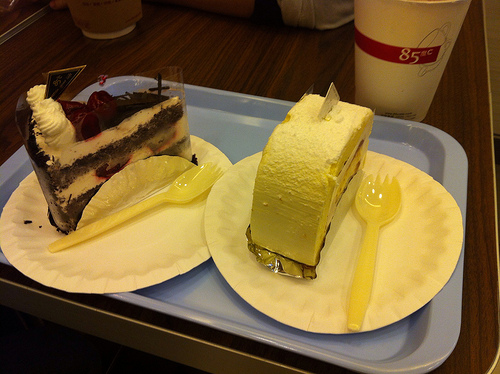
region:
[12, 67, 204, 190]
Dessert on a paper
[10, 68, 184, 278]
Dessert on a paper plate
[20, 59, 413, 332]
Two desserts on paper plates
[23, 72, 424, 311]
Two desserts on a purple tray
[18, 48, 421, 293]
Two desserts with plastic utensils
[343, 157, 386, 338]
A yellow plastic utensil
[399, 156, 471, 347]
A paper plate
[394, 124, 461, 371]
A paper plate on a purple tray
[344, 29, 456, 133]
A paper cup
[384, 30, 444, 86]
White numbers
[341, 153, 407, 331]
a yellow plastic spork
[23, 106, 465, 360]
some white paper plates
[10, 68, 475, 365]
a blue plastic tray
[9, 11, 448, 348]
a few deserts on togo settings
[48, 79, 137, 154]
a few cooked cherries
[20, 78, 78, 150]
some whip cream toppings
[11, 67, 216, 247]
a chocolate layered cake slice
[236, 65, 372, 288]
a yellow cake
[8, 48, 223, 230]
a plastic wrapper on cake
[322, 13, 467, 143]
a disposable cup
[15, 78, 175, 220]
this is a cake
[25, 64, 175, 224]
the cake is brown in color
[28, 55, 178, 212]
the cake is creamy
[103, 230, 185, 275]
this is a plate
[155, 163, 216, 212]
this is spoon beside the cake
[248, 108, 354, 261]
the cake is yellow in color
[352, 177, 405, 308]
the spoon is yellow in color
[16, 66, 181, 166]
the cake is big in size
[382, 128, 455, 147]
the tray is blue in color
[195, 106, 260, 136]
the tray is flat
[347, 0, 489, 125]
white beverage cup on table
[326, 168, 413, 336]
yellow plastic spork on paper plate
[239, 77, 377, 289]
piece of white layered cake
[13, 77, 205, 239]
piece of chocolate layered cake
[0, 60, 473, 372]
two pieces of cake on blue tray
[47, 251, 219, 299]
edge of white paper plate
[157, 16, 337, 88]
brown wooden table food is on top of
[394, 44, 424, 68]
the number 85 printed on cup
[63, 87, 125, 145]
red cherries on top of cake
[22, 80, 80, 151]
white cream piped on top of cake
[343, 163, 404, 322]
this is a spoon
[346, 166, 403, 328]
the spoon is cream in color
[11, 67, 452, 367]
this is a try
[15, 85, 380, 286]
this is a cake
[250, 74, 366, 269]
the cake is cream in color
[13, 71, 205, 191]
the cake is brown and cream in color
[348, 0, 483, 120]
this is a cup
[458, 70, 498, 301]
this is a table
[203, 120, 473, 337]
this is a plate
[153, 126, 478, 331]
the plate is cream in color